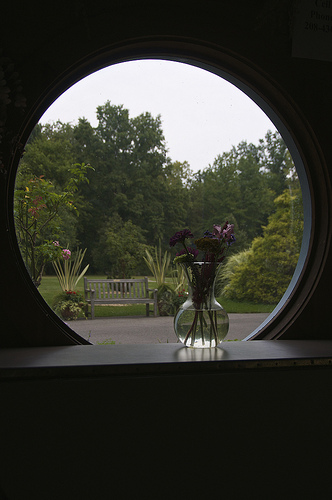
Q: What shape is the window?
A: Round.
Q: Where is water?
A: In a vase.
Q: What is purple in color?
A: Flowers.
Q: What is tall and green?
A: Trees.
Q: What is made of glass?
A: The vase.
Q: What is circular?
A: A window.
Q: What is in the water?
A: Stems of flowers.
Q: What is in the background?
A: Many trees.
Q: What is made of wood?
A: A bench.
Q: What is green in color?
A: The grass.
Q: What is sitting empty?
A: The bench.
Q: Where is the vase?
A: On counter.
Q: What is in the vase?
A: Flowers.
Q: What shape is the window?
A: A circle.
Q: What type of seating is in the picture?
A: A bench.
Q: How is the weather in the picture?
A: Overcast.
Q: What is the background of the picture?
A: Trees.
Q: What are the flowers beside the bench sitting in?
A: Pots.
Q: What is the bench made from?
A: Wood.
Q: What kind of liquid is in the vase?
A: Water.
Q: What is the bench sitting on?
A: Sidewalk.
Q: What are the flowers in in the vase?
A: Water.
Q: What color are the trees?
A: Green.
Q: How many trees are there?
A: More than two.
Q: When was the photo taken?
A: Daytime.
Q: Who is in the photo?
A: No one.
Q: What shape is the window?
A: Circular.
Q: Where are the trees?
A: In the backyard.